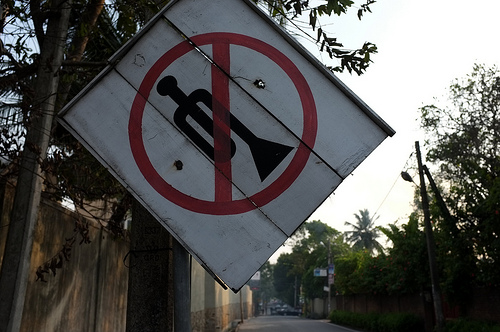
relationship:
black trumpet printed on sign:
[156, 74, 295, 183] [57, 5, 398, 295]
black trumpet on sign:
[153, 70, 295, 188] [57, 5, 398, 295]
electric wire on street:
[366, 136, 445, 228] [234, 312, 353, 329]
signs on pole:
[313, 265, 325, 277] [324, 235, 334, 315]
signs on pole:
[56, 4, 398, 294] [1, 2, 71, 330]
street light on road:
[405, 137, 478, 329] [253, 306, 318, 328]